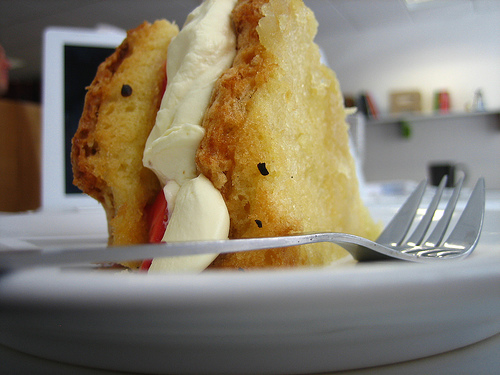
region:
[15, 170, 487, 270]
a fork is on a plate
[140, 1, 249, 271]
white cream in food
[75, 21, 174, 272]
a piece of bread like material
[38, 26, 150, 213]
a screen in the distance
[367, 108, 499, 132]
a shelf in the distance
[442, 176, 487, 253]
a prong on a fork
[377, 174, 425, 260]
a prong on a fork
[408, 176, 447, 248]
a prong on a fork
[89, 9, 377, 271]
a desert food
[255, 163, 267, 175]
piece of burnt food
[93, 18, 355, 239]
A delicious looking cake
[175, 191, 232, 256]
A white creame of cake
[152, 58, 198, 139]
A white creame of cake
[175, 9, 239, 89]
A white creame of cake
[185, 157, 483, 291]
A silver shiny fork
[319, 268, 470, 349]
A white plate surface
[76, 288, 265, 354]
A white plate surface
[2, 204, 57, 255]
A white plate surface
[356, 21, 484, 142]
A unclear photo backgorund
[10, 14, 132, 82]
A unclear photo backgorund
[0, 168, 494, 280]
a fork on the plate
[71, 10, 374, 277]
a sandwich on the plate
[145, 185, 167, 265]
a tomato in the sandwich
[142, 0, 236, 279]
cream in the sandwich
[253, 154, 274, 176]
a black spot on the sandwich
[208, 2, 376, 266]
the bread is toasted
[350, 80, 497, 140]
a shelf on the wall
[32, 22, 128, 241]
a laptop behind the sandwich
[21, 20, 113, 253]
the laptop is white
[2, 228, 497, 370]
the plate is white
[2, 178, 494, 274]
the silver metal fork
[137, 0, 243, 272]
the white whipped cream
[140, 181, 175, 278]
the red sliced strawberry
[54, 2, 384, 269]
the crispy pastry with cream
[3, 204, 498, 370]
the flat white plate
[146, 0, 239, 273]
the whipped cream and strawberry desert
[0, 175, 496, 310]
the fork is on the plate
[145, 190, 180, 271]
the strawberry is covered by cream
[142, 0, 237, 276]
the whipped cream is thick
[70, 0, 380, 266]
the pastry is filled with cream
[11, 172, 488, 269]
a silver fork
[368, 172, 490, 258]
four prongs on the fork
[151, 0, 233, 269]
white custard on the food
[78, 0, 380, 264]
a meal on the plate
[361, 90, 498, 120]
a shelf for storage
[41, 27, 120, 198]
a white framed doorway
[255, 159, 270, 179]
black speck on the food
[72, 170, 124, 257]
a bite is missing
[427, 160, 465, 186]
a black coffee cup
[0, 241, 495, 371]
a plain white plate